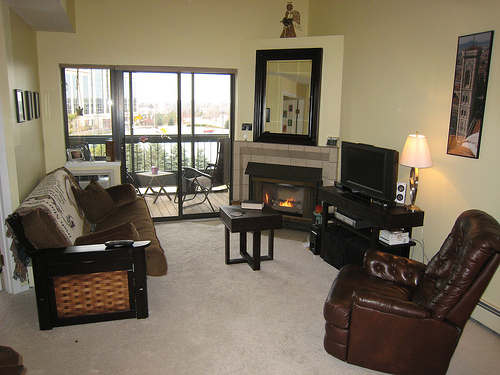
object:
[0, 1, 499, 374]
room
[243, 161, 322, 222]
fireplace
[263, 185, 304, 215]
place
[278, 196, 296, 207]
fire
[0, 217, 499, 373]
carpet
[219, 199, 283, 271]
table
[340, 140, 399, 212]
tv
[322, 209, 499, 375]
chair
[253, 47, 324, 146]
mirror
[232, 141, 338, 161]
mantle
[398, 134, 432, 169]
lampshade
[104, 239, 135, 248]
remote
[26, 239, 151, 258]
armrest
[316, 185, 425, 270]
stand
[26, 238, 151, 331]
end table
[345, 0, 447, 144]
wall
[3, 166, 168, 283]
sofa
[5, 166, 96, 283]
blanket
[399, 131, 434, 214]
lamp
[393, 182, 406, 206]
speakers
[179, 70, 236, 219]
door pane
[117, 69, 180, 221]
door pane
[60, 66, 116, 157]
door pane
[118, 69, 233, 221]
door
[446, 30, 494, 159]
picture frame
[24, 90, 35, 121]
picture frame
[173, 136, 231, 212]
chair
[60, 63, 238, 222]
balcony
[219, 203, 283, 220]
table top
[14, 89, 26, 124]
frames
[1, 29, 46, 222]
wall